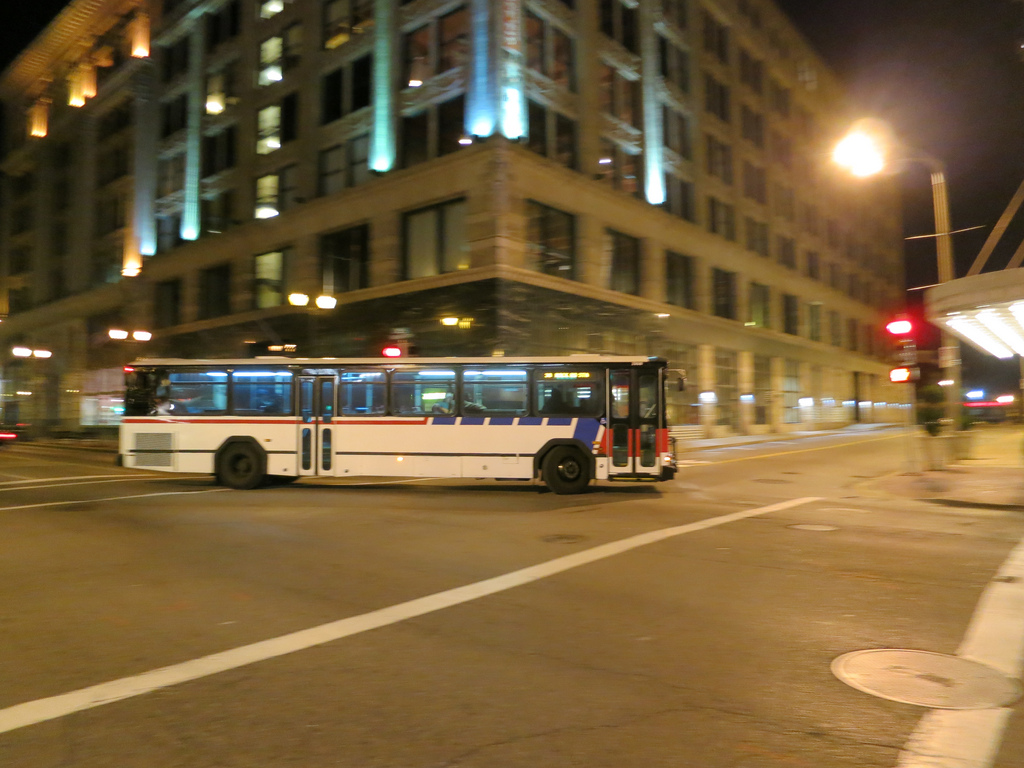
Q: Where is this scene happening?
A: Dark city night.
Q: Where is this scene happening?
A: At a crosswalk.